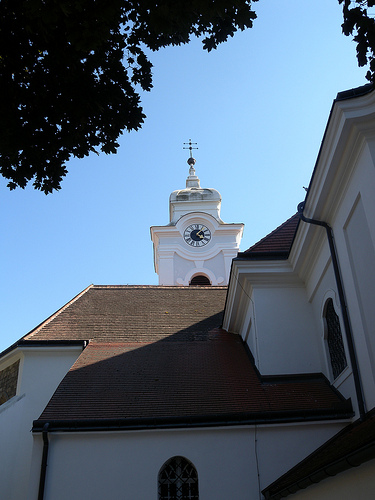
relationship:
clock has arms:
[184, 224, 213, 247] [197, 232, 209, 244]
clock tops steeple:
[184, 224, 213, 247] [150, 139, 245, 287]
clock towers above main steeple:
[184, 224, 213, 247] [150, 139, 245, 287]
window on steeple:
[320, 300, 351, 382] [150, 139, 245, 287]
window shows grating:
[156, 456, 198, 498] [173, 464, 185, 499]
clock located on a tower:
[184, 224, 213, 247] [150, 139, 238, 283]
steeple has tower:
[150, 139, 245, 287] [150, 139, 238, 283]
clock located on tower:
[184, 224, 213, 247] [150, 139, 238, 283]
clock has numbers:
[184, 224, 213, 247] [203, 229, 211, 247]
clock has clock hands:
[184, 224, 213, 247] [197, 232, 209, 244]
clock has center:
[184, 224, 213, 247] [192, 230, 204, 240]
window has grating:
[156, 456, 198, 498] [173, 464, 185, 499]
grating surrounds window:
[173, 464, 185, 499] [156, 456, 198, 498]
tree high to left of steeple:
[0, 0, 258, 194] [150, 139, 245, 287]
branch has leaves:
[337, 1, 374, 81] [355, 33, 368, 67]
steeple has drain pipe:
[150, 139, 245, 287] [299, 190, 369, 416]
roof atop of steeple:
[31, 288, 356, 431] [150, 139, 245, 287]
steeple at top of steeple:
[150, 139, 238, 283] [150, 139, 245, 287]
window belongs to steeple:
[320, 300, 351, 382] [150, 139, 245, 287]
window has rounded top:
[320, 300, 351, 382] [320, 299, 340, 326]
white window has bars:
[156, 456, 198, 498] [164, 479, 198, 496]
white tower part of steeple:
[150, 139, 238, 283] [150, 139, 245, 287]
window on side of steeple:
[320, 300, 351, 382] [150, 139, 245, 287]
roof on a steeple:
[31, 288, 356, 431] [150, 139, 245, 287]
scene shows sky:
[3, 3, 374, 500] [192, 46, 301, 163]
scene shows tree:
[3, 3, 374, 500] [0, 0, 258, 194]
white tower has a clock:
[150, 139, 238, 283] [184, 224, 213, 247]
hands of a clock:
[197, 232, 209, 244] [184, 224, 213, 247]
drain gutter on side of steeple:
[299, 190, 369, 416] [150, 139, 245, 287]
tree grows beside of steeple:
[0, 0, 258, 194] [150, 139, 245, 287]